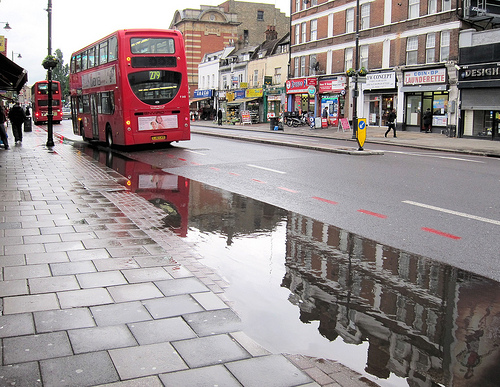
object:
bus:
[70, 28, 192, 150]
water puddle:
[65, 140, 498, 386]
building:
[285, 213, 498, 386]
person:
[9, 97, 28, 145]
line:
[246, 160, 287, 177]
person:
[424, 107, 433, 134]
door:
[419, 94, 434, 135]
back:
[9, 106, 27, 123]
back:
[119, 28, 189, 146]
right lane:
[38, 115, 471, 358]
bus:
[30, 79, 64, 126]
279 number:
[146, 70, 163, 83]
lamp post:
[46, 0, 56, 146]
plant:
[40, 54, 59, 70]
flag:
[354, 116, 370, 149]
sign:
[244, 86, 265, 97]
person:
[0, 101, 10, 151]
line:
[312, 191, 340, 208]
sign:
[286, 78, 316, 92]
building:
[287, 0, 461, 137]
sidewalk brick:
[25, 271, 81, 295]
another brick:
[73, 268, 131, 291]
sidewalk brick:
[67, 316, 138, 356]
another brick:
[124, 312, 202, 347]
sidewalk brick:
[156, 363, 246, 386]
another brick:
[222, 351, 312, 386]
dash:
[419, 225, 461, 242]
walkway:
[189, 124, 384, 156]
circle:
[358, 120, 365, 131]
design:
[459, 62, 499, 82]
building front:
[455, 2, 499, 144]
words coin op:
[410, 66, 439, 77]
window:
[127, 70, 184, 106]